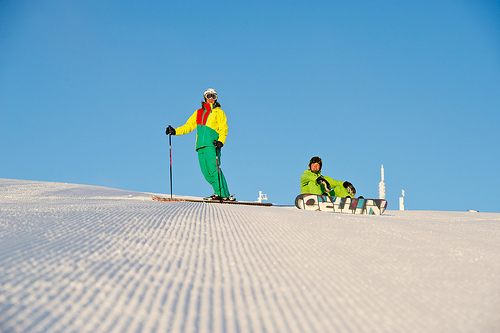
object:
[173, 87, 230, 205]
person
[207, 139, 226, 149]
gloves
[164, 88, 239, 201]
woman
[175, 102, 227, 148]
jacket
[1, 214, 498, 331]
snow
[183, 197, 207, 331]
groove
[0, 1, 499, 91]
sky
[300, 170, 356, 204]
jacket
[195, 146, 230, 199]
pants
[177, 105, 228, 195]
clothes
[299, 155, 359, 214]
man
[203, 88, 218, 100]
helmet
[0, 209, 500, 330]
ground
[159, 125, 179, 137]
gloves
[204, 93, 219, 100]
goggles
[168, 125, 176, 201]
ski poles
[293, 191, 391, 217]
snowboard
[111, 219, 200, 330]
tracks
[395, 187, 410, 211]
creation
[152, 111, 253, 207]
skis